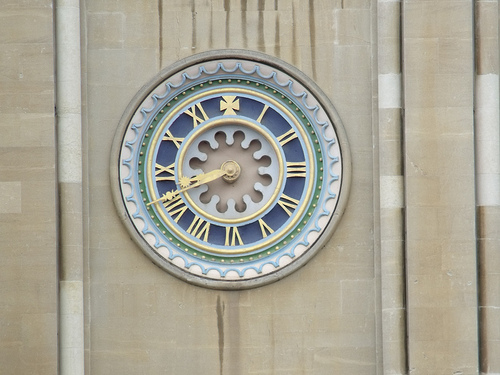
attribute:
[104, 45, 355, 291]
circle — green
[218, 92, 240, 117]
cross —  iron,  number 12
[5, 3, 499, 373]
building — side,  stone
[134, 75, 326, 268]
clock face —  gold, dark blue, and light blue, of clock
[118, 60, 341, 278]
design — wave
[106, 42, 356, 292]
clock —  old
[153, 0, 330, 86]
stains — water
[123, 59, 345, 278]
decoration — blue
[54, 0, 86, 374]
bricks —  light grey,  vertical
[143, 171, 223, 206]
hands —  gold, for minute and hour 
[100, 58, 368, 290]
clock — blue and white